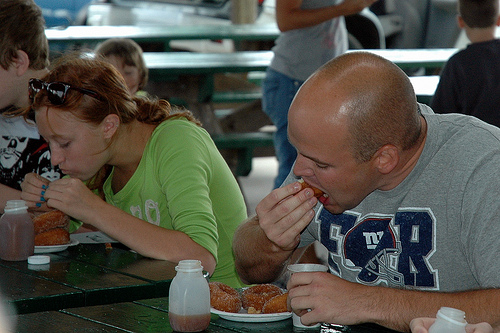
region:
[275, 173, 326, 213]
Man eating a dough nut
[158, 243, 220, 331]
Jug of juice on a green table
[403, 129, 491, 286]
Man wearing a gray tee shirt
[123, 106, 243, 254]
Woman wearing a green shirt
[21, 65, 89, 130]
Woman with sunglasses on her head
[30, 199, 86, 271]
Woman with a plate of donuts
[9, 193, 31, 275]
Jug of juice in front of a woman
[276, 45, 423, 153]
Man with a bald head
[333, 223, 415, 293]
NY Giants helmet on a tee shirt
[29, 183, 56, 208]
Woman with blue finger nails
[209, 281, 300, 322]
Three doughnuts are on the plate.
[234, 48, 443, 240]
The man is eating a doughnut.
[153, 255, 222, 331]
The jar has juice inside it.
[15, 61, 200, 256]
The woman is eating a doughnut.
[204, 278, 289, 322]
The doughnuts are on a white plate.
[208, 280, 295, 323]
The doughnuts have sugar on them.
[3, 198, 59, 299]
The juice bottle is open.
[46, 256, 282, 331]
The food is on the table.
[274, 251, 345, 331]
The man has a cup in his hand.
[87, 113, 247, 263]
The woman's shirt is green.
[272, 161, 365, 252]
man eating a dough nut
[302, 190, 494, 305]
man wearing a gray shirt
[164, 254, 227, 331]
Jug with juice on the table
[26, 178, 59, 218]
woman with blue finger nails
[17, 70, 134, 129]
woman wearing sunglasses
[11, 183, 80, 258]
donuts on a plate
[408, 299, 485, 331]
person holding a jug of juice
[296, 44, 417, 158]
man with a bald head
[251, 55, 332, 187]
person wearing blue jeans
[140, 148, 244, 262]
woman wearing a green tee shir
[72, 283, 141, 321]
this is a table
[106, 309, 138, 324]
the table is black in color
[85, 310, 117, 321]
the table is wooden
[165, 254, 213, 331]
this is a bottle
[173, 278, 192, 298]
the bottle is made of palstic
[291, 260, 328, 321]
this is a cup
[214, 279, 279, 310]
these are some doughnuts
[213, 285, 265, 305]
the doughnuts are small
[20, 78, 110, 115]
these are some sunglasses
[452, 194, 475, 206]
the t-shirt is grey in color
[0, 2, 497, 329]
people sitting at table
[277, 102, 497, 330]
gray shirt with logo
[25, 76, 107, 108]
glasses on woman's head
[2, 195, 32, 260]
plastic container with liquid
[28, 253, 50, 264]
white cap on table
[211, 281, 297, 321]
donuts on white plate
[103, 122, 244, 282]
green shirt with white on front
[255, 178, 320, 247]
donut placed in mouth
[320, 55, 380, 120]
shine on man's head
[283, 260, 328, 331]
cup in man's hand